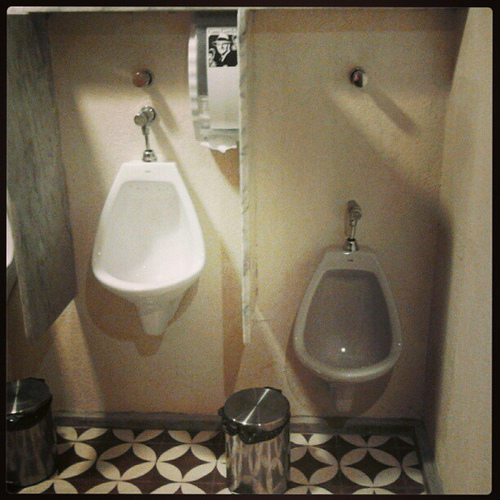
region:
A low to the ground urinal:
[281, 195, 448, 448]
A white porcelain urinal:
[81, 99, 207, 354]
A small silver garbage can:
[208, 383, 290, 495]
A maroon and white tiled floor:
[67, 427, 416, 498]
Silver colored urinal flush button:
[322, 194, 374, 258]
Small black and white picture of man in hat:
[205, 30, 237, 74]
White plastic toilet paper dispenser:
[181, 31, 237, 154]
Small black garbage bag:
[209, 396, 296, 446]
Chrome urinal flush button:
[120, 60, 165, 100]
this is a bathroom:
[3, 30, 479, 487]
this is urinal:
[80, 78, 226, 343]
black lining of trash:
[215, 401, 290, 454]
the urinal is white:
[75, 86, 217, 361]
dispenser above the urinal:
[167, 21, 260, 206]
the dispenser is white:
[165, 15, 263, 186]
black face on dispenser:
[200, 17, 242, 79]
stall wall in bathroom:
[196, 0, 287, 342]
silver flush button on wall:
[339, 55, 380, 102]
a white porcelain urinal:
[89, 161, 206, 336]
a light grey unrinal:
[288, 247, 403, 412]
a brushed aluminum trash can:
[221, 386, 289, 495]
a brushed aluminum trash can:
[0, 375, 60, 487]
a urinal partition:
[235, 8, 250, 345]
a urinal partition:
[6, 16, 76, 343]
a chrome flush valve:
[133, 107, 155, 160]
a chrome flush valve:
[343, 198, 358, 251]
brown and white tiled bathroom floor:
[8, 427, 425, 497]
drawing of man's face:
[208, 32, 237, 67]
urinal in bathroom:
[287, 232, 404, 412]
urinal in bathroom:
[85, 159, 211, 339]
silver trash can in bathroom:
[211, 381, 295, 494]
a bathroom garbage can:
[217, 382, 294, 497]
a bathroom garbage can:
[8, 369, 71, 484]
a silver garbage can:
[198, 370, 328, 486]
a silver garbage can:
[19, 362, 61, 493]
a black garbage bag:
[193, 391, 303, 489]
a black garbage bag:
[11, 370, 71, 462]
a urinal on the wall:
[284, 193, 447, 447]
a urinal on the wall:
[79, 157, 188, 312]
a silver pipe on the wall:
[342, 200, 359, 243]